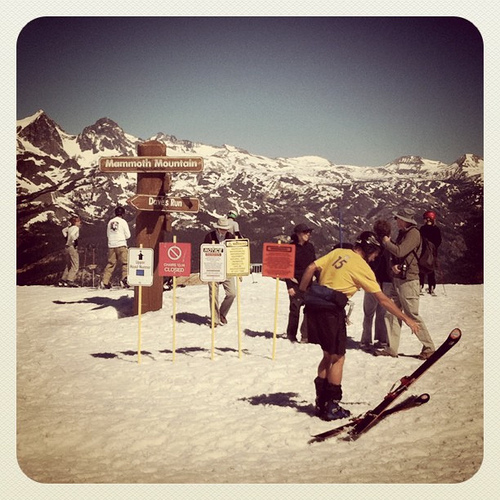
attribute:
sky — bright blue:
[44, 30, 445, 122]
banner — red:
[261, 242, 295, 277]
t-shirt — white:
[107, 217, 130, 249]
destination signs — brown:
[96, 142, 206, 174]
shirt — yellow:
[310, 252, 375, 291]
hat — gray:
[207, 210, 234, 232]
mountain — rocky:
[20, 101, 481, 279]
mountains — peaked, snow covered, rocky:
[6, 135, 482, 282]